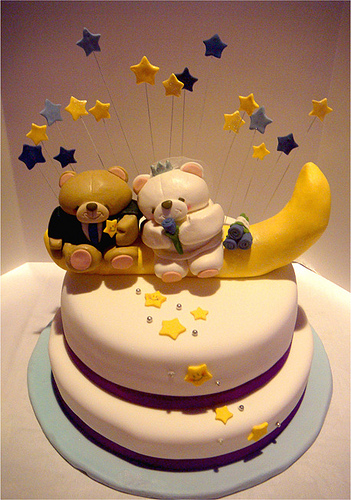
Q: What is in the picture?
A: A cake.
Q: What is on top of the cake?
A: Teddy bears and stars.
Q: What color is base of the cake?
A: Blue.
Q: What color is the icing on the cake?
A: White.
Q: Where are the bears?
A: On top of the cake.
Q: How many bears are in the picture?
A: Two.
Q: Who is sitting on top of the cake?
A: Teddy bears.